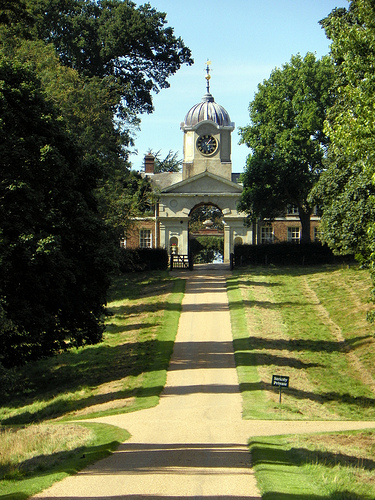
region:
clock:
[0, 135, 37, 160]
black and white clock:
[191, 128, 221, 161]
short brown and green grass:
[11, 436, 74, 475]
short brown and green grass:
[72, 383, 114, 408]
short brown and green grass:
[279, 446, 334, 476]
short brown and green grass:
[330, 444, 366, 497]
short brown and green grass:
[291, 311, 325, 336]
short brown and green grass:
[326, 347, 351, 394]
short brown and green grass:
[262, 290, 309, 325]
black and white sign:
[266, 365, 296, 397]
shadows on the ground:
[97, 305, 368, 413]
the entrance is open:
[169, 191, 231, 282]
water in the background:
[186, 220, 224, 273]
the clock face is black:
[180, 120, 227, 167]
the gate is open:
[156, 242, 202, 273]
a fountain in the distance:
[181, 204, 226, 240]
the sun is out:
[122, 362, 257, 456]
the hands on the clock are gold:
[182, 132, 223, 159]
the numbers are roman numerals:
[181, 132, 223, 155]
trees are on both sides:
[4, 17, 372, 417]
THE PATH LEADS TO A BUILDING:
[1, 268, 374, 497]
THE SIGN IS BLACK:
[265, 366, 294, 408]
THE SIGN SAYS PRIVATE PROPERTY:
[271, 365, 294, 401]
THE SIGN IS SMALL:
[269, 371, 290, 405]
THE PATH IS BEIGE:
[19, 271, 374, 499]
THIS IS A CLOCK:
[196, 133, 224, 161]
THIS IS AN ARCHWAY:
[183, 195, 229, 271]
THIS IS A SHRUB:
[234, 236, 339, 274]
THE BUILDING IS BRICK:
[105, 60, 368, 268]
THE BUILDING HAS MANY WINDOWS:
[101, 52, 352, 272]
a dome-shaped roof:
[181, 91, 253, 151]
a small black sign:
[264, 356, 308, 411]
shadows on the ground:
[145, 259, 306, 479]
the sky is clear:
[147, 115, 175, 171]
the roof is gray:
[171, 104, 248, 149]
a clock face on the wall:
[190, 119, 230, 180]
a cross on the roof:
[187, 47, 225, 126]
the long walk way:
[164, 254, 262, 455]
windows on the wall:
[252, 203, 308, 257]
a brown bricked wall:
[249, 200, 344, 252]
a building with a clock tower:
[86, 58, 350, 277]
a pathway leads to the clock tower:
[157, 266, 253, 455]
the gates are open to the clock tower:
[167, 247, 240, 276]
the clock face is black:
[195, 133, 218, 157]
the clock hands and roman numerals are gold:
[195, 131, 217, 158]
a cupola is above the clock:
[177, 94, 237, 129]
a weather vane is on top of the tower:
[199, 55, 216, 74]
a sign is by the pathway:
[268, 373, 290, 392]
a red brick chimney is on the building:
[142, 152, 157, 178]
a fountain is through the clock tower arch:
[190, 200, 226, 264]